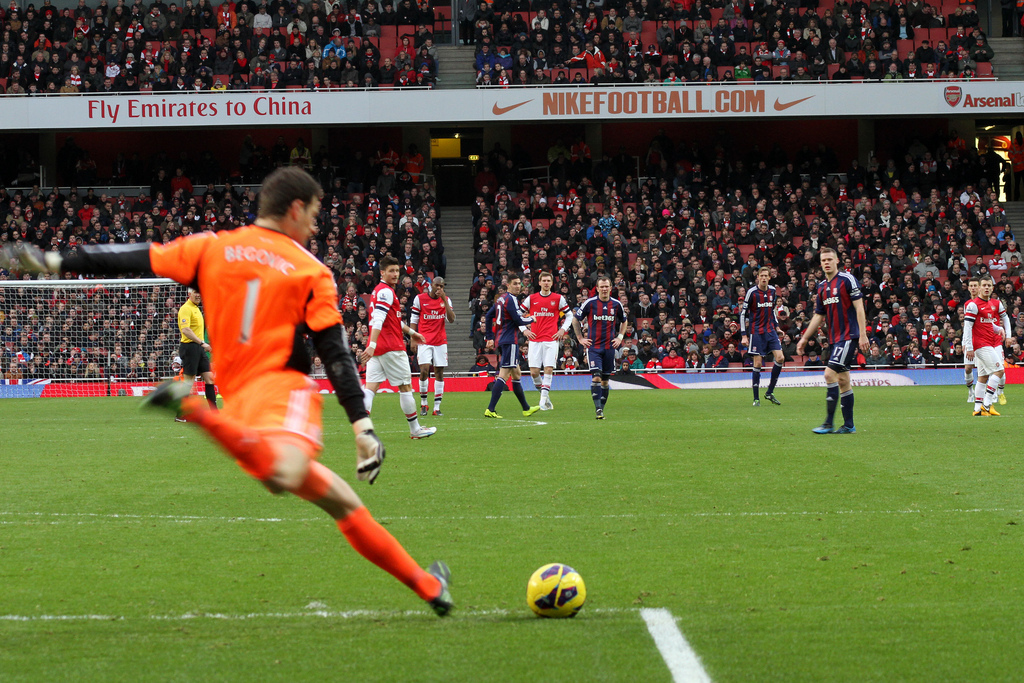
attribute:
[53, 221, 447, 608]
uniform — orange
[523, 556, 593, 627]
ball — blue, yellow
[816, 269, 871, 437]
uniform — maroon, black, red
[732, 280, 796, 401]
uniform — maroon, black, red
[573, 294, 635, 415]
uniform — maroon, black, red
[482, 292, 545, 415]
uniform — maroon, black, red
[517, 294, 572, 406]
uniform — red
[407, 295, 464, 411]
uniform — red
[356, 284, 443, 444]
uniform — red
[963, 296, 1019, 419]
uniform — red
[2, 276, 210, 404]
net — white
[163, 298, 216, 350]
shirt — yellow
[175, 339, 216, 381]
pants — black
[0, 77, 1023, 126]
advertisement — white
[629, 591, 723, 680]
line — white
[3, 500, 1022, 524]
line — white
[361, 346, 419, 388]
shorts — white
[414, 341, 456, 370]
shorts — white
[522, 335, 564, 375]
shorts — white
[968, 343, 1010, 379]
shorts — white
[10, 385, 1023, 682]
field — green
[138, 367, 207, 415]
cleats — dark